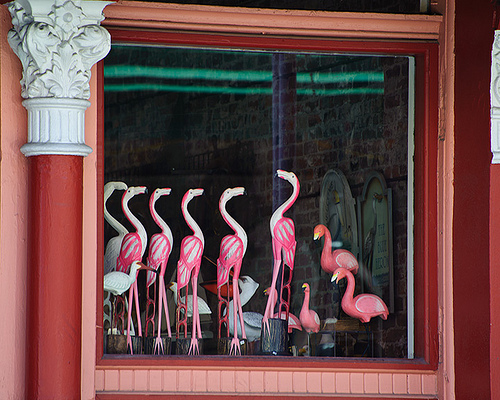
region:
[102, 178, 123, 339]
flamingo in front of window display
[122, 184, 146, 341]
flamingo in front of window display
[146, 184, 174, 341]
flamingo in front of window display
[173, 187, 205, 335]
flamingo in front of window display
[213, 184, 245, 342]
flamingo in front of window display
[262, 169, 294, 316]
flamingo in front of window display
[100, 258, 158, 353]
bird in front of window display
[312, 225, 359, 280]
bird in front of window display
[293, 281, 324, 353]
bird in front of window display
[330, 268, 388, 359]
bird in front of window display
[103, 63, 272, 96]
Green reflection on the window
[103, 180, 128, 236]
A white flamingo's head and neck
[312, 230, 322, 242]
A beak of a flamingo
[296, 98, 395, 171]
A reflection of bricks on the window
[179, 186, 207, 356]
Pink and white fake flamingo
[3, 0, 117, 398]
Red and white column on the building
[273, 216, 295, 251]
Pink and white wing on flamingo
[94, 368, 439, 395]
Pink brick on the bottom of the window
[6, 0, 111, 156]
Detailed carvings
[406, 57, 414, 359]
White paint along the window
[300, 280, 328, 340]
flamingo in the window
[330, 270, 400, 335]
flamingo in the window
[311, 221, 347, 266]
flamingo in the window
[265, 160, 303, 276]
flamingo in the window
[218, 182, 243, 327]
flamingo in the window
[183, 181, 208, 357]
flamingo in the window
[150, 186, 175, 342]
flamingo in the window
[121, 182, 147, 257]
flamingo in the window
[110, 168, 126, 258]
flamingo in the window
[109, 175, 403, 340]
birds in the window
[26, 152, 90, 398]
the column is red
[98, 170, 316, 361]
flamingos drawings on the glass